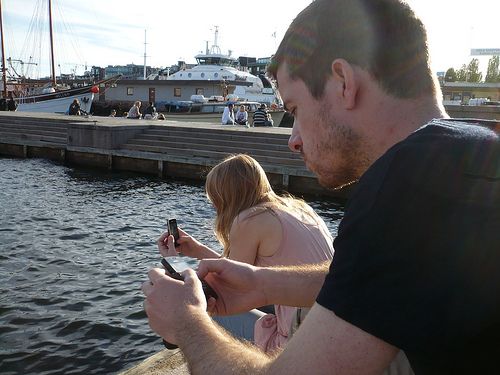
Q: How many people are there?
A: Two.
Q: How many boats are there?
A: One.